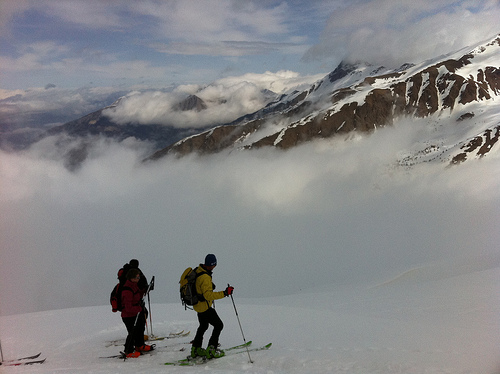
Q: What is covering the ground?
A: Snow.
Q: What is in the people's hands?
A: Ski poles.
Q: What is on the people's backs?
A: Backpacks.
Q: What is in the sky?
A: Clouds.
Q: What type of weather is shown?
A: Cold and cloudy.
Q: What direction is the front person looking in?
A: To their left.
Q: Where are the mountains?
A: Right side of the image.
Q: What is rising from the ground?
A: Fog.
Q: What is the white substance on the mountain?
A: Snow.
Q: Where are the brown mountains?
A: Under snow.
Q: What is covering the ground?
A: Snow.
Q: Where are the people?
A: In mountains.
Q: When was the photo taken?
A: Winter.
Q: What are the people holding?
A: Ski poles.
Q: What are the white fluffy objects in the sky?
A: Clouds.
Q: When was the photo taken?
A: Winter.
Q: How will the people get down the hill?
A: Skis.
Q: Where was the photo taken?
A: Mountains.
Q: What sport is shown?
A: Skiing.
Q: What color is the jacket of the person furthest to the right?
A: Yellow.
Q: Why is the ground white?
A: Snow.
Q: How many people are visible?
A: Three.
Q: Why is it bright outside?
A: It's daytime.